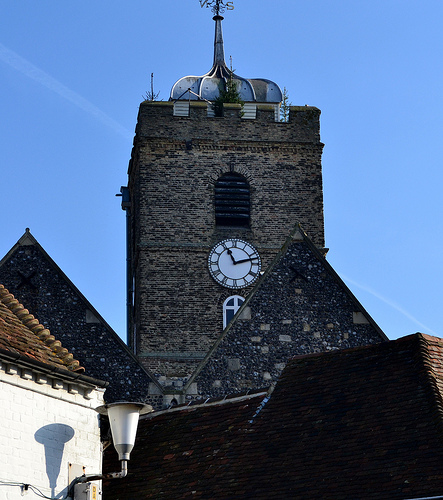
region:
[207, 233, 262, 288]
a clock on the building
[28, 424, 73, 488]
a shadow on the wall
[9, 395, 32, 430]
building made of bricks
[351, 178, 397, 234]
a clear sky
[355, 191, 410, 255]
a clear blue sky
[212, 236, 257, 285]
a clock on a building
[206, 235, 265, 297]
an outside clock on a building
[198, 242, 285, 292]
a large clock on a building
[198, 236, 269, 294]
a large outside clock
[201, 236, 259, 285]
a building with a clock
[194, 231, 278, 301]
a building with an outside clock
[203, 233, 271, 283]
a building with an outside clock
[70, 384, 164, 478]
a light on a building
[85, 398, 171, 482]
an outside light on a building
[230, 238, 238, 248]
black roman numeral on clock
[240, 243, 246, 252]
black roman numeral on clock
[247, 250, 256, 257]
black roman numeral on clock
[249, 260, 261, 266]
black roman numeral on clock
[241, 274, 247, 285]
black roman numeral on clock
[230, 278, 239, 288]
black roman numeral on clock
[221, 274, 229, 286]
black roman numeral on clock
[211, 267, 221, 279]
black roman numeral on clock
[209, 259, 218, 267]
black roman numeral on clock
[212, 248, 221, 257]
black roman numeral on clock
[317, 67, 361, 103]
white clouds in blue sky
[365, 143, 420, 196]
white clouds in blue sky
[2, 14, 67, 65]
white clouds in blue sky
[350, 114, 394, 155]
white clouds in blue sky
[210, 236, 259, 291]
clock on side of brick tower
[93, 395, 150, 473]
outdoor light fixture on side of building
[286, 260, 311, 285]
X design on the side of old stonework building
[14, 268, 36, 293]
X design on the side of old stonework building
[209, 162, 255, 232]
arched window over clock with slats and no glass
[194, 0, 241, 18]
weather vane on very top of a brick tower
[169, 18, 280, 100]
"onion" style dome on top of old brick tower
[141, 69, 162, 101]
lightning rod on top of old tower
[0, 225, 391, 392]
two steeply pointed roofs of stonework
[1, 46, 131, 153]
jet trail from airplane to left of tower in blue sky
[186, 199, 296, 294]
round clock on building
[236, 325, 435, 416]
top of the roof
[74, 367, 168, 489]
light on a building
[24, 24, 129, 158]
sky above the land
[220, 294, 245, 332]
a blue colored window with white trim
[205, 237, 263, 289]
a round clock showing the time as 11:12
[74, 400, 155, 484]
a round light fixture on a metal attachment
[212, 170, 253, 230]
a window with black colored slats over it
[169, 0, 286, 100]
a silver colored weather vane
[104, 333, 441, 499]
a reddish brown colored shingled roof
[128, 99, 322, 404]
a tall brick tower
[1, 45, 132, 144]
a trail left by a flying jet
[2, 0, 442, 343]
a clear blue colored sky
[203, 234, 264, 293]
black and white clock on building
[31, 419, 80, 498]
shadow of street light on building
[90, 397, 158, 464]
white metal street light on side of building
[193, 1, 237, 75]
weather vane on top of building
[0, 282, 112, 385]
brown ridged roof on building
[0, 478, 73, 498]
street lamp wire on side of building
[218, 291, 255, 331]
arched white framed window underneath clock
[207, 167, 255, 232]
brown arched window on top of clock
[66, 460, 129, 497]
metal pole attached to street light